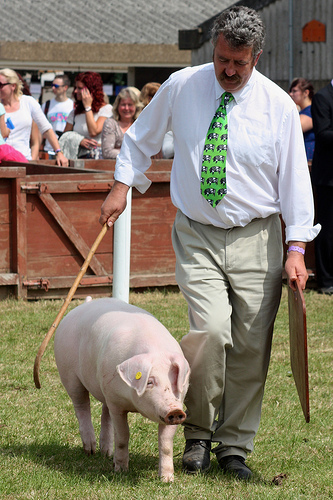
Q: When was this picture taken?
A: Daytime.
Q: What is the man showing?
A: A pig.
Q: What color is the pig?
A: Pink.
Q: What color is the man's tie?
A: Green.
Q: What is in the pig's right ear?
A: A tag.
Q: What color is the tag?
A: Yellow.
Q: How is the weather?
A: Sunny.